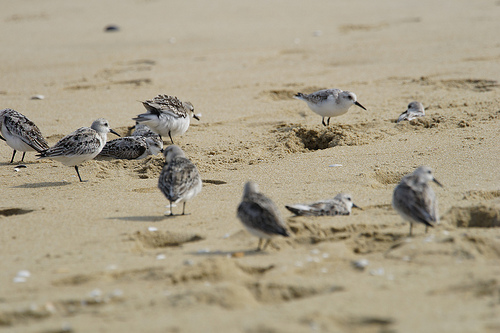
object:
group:
[0, 84, 451, 248]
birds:
[388, 165, 448, 236]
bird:
[154, 147, 205, 216]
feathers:
[142, 87, 187, 116]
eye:
[103, 122, 109, 126]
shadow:
[107, 211, 163, 225]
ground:
[0, 29, 500, 291]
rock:
[29, 92, 44, 101]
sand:
[44, 40, 184, 88]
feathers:
[35, 149, 48, 159]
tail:
[35, 150, 55, 159]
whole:
[447, 200, 497, 237]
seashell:
[395, 91, 439, 127]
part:
[172, 53, 228, 64]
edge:
[67, 150, 100, 155]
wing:
[60, 134, 101, 157]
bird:
[284, 190, 363, 220]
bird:
[37, 117, 120, 183]